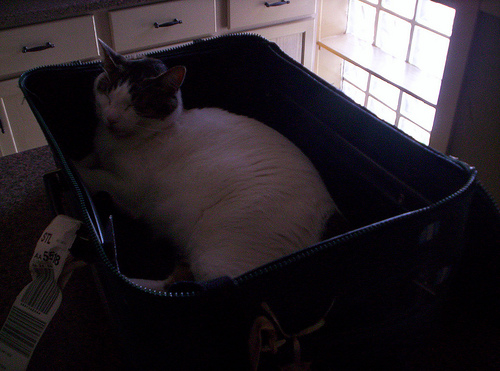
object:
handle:
[153, 17, 181, 28]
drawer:
[0, 15, 103, 78]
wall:
[435, 8, 498, 193]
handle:
[262, 0, 288, 10]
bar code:
[13, 257, 72, 318]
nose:
[103, 112, 120, 123]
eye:
[98, 84, 109, 102]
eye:
[124, 99, 138, 112]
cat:
[90, 36, 341, 291]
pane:
[406, 23, 452, 78]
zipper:
[97, 244, 196, 311]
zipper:
[56, 35, 223, 68]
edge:
[444, 157, 480, 206]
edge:
[109, 263, 197, 311]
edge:
[228, 27, 274, 47]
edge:
[13, 60, 35, 97]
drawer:
[227, 0, 317, 30]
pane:
[397, 93, 436, 137]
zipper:
[434, 168, 479, 206]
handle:
[22, 38, 54, 55]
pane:
[373, 14, 410, 58]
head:
[94, 39, 181, 121]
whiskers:
[68, 94, 173, 147]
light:
[382, 22, 401, 49]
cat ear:
[155, 56, 197, 92]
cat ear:
[93, 34, 122, 67]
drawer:
[111, 0, 218, 52]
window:
[317, 0, 460, 148]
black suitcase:
[17, 32, 499, 368]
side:
[358, 240, 415, 272]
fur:
[132, 114, 334, 276]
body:
[168, 110, 290, 245]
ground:
[189, 54, 463, 301]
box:
[18, 29, 474, 366]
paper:
[0, 210, 88, 370]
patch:
[90, 47, 183, 121]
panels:
[343, 0, 379, 46]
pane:
[340, 58, 371, 97]